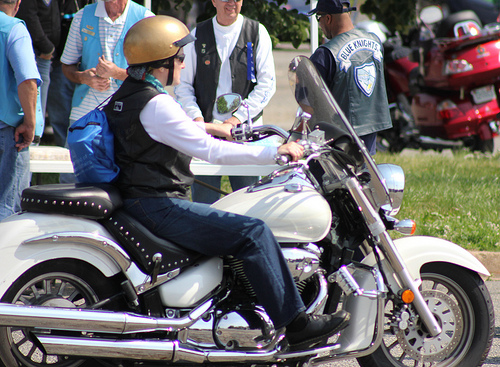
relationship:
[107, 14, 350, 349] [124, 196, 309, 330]
cyclist wearing jeans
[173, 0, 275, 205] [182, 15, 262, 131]
people wearing vest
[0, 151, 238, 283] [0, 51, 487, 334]
seat of motorcycle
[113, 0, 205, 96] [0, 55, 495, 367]
helmet of bike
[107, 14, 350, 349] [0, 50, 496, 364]
cyclist riding motorcycle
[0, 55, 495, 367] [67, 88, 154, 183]
bike has backpack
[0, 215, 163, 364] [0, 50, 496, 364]
wheel of motorcycle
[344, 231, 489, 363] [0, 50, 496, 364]
wheel of motorcycle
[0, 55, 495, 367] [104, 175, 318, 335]
bike wearing jeans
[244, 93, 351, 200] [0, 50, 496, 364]
bar of motorcycle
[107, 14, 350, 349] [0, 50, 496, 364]
cyclist sitting on motorcycle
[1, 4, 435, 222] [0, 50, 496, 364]
people standing next to motorcycle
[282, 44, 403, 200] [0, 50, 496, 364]
windshield on motorcycle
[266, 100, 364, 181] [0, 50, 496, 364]
bars on motorcycle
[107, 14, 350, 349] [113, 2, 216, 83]
cyclist wearing helmet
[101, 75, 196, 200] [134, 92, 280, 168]
jacket over shirt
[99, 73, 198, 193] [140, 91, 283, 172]
vest over shirt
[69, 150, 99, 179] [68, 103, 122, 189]
lettering on backpack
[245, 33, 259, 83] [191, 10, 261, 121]
ribbon on vest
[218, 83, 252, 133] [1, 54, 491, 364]
sideview mirror on bike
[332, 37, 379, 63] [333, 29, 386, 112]
biker-gang name on back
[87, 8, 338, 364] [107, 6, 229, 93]
cyclist with helmet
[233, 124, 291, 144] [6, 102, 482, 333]
bar on motorcycle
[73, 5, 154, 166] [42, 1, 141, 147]
person with vest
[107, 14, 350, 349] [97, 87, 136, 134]
cyclist with emblem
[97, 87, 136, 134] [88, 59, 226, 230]
emblem on jacket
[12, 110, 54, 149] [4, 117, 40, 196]
hand on hip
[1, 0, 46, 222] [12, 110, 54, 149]
people with hand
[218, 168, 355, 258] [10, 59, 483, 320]
tank of motorcycle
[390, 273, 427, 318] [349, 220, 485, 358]
reflector on wheel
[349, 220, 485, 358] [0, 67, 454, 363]
wheel of motorcycle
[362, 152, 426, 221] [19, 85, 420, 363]
headlight of motorcycle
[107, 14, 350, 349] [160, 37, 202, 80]
cyclist wearing sunglasses